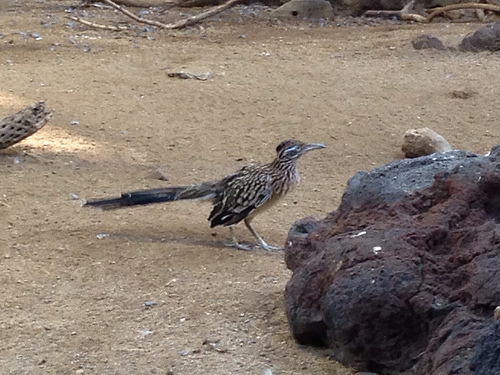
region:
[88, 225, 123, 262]
part of a ground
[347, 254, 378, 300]
part of a roack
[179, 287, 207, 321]
part of a ground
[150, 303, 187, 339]
part of a ground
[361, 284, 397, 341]
part of a stone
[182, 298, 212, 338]
part of a ground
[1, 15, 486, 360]
A bird is walking around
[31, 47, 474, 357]
A bird is looking for food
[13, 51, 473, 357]
A bird is finding its nest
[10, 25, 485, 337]
The bird is on dry land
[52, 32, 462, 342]
The bird is looking for its mate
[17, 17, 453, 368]
The bird is hunting something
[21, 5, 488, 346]
The bird has colorful feathers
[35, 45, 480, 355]
The bird is close to a rock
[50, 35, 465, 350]
The bird has long tail feathers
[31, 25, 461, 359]
The bird has a sharp beak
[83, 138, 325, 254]
bird standing on the sand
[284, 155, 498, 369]
large gray lava rock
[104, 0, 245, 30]
dead broken branch on the ground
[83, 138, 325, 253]
bird has a long black tailfeather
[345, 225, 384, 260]
bird poop on top of rock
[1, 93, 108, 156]
sun shining on the beach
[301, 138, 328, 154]
long pointed beak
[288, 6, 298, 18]
round hole in side of rock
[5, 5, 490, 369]
sandy and rocky tan beach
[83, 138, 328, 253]
birds feathers are speckled in white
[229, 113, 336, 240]
the bird is looking up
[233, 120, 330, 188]
the bird is looking up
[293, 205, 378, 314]
the rock is brown and gray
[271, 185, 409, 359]
the rock is brown and gray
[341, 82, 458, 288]
the rock is brown and gray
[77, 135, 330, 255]
roadrunner bird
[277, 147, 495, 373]
large reddish desert rock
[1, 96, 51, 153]
piece of ocotillo cactus skeleton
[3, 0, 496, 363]
Roadrunner bird in desert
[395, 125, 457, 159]
desert rock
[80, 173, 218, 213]
Roadrunner's long tail used to balance while running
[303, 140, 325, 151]
pointed yellow bird's beak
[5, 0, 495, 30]
several dead tree branches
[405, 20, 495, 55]
two dark desert rocks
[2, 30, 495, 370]
desert floor dirt ground